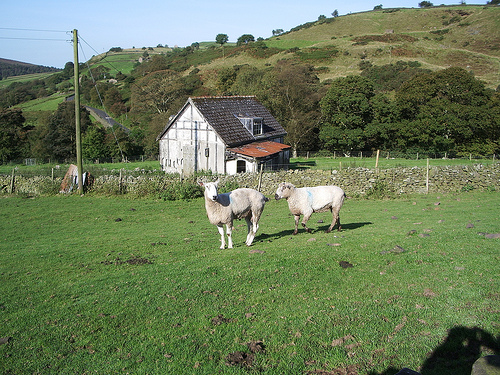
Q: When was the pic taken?
A: During the day.